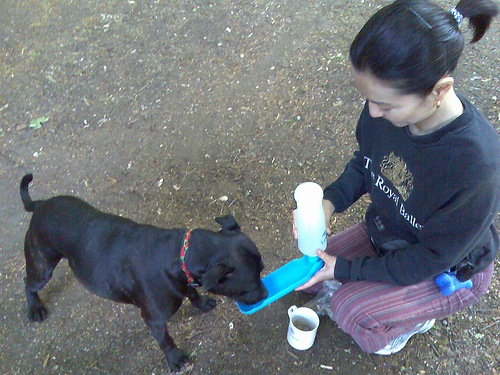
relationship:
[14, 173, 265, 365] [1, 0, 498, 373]
dog on ground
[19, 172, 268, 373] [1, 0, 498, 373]
black dog on ground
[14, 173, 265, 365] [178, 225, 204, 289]
dog wearing collar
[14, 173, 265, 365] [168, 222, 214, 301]
dog wearing collar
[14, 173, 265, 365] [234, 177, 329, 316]
dog drinking from water bottle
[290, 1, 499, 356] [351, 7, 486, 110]
woman has woman's hair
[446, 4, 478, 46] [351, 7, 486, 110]
rubber band in woman's hair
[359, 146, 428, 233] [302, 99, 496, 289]
design on sweatshirt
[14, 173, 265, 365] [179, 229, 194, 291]
dog wearing collar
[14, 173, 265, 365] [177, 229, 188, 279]
dog wearing red collar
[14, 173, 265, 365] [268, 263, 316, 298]
dog drinking water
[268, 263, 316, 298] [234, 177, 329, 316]
water in water bottle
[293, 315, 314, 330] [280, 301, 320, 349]
water in cup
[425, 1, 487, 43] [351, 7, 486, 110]
ponytail in woman's hair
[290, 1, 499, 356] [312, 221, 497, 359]
woman wearing striped pants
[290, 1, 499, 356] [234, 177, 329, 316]
woman holding water bottle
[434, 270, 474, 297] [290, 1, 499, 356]
dog bone clipped to woman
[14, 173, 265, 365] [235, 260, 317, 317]
dog drinking from bowl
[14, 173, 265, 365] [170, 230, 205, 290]
dog wearing collar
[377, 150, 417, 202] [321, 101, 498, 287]
logo on shirt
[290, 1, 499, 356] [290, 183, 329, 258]
woman holding blue bottle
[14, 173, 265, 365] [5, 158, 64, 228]
dog has tail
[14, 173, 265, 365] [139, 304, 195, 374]
dog has leg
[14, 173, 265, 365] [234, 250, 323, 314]
dog eating from dish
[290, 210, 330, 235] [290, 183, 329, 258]
hand holding blue bottle